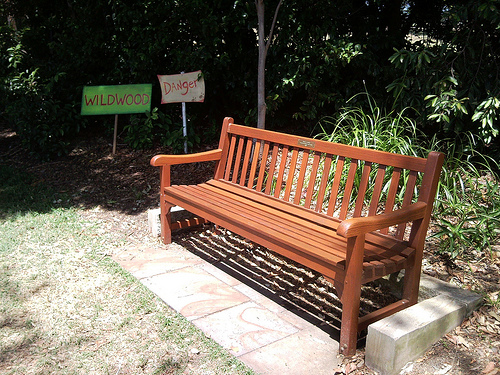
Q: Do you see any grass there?
A: Yes, there is grass.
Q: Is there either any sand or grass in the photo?
A: Yes, there is grass.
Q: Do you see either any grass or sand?
A: Yes, there is grass.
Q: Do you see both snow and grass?
A: No, there is grass but no snow.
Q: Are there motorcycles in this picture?
A: No, there are no motorcycles.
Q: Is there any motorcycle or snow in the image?
A: No, there are no motorcycles or snow.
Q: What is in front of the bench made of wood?
A: The grass is in front of the bench.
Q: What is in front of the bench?
A: The grass is in front of the bench.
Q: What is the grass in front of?
A: The grass is in front of the bench.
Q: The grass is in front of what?
A: The grass is in front of the bench.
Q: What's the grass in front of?
A: The grass is in front of the bench.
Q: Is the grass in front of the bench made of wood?
A: Yes, the grass is in front of the bench.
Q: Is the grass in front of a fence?
A: No, the grass is in front of the bench.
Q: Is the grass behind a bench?
A: No, the grass is in front of a bench.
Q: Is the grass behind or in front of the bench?
A: The grass is in front of the bench.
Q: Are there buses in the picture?
A: No, there are no buses.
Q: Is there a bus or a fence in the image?
A: No, there are no buses or fences.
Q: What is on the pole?
A: The sign is on the pole.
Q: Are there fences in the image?
A: No, there are no fences.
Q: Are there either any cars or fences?
A: No, there are no fences or cars.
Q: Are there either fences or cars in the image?
A: No, there are no fences or cars.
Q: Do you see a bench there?
A: Yes, there is a bench.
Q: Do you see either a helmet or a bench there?
A: Yes, there is a bench.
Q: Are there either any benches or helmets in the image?
A: Yes, there is a bench.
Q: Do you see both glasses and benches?
A: No, there is a bench but no glasses.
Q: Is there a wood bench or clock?
A: Yes, there is a wood bench.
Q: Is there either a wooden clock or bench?
A: Yes, there is a wood bench.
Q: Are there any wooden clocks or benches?
A: Yes, there is a wood bench.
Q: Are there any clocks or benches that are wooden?
A: Yes, the bench is wooden.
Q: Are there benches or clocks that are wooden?
A: Yes, the bench is wooden.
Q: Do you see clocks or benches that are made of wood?
A: Yes, the bench is made of wood.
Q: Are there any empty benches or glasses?
A: Yes, there is an empty bench.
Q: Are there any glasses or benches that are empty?
A: Yes, the bench is empty.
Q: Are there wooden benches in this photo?
A: Yes, there is a wood bench.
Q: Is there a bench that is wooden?
A: Yes, there is a bench that is wooden.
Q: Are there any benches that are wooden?
A: Yes, there is a bench that is wooden.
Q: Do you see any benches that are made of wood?
A: Yes, there is a bench that is made of wood.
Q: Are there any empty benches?
A: Yes, there is an empty bench.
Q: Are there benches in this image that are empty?
A: Yes, there is a bench that is empty.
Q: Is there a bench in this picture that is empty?
A: Yes, there is a bench that is empty.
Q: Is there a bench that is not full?
A: Yes, there is a empty bench.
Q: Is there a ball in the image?
A: No, there are no balls.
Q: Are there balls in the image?
A: No, there are no balls.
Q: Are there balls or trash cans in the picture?
A: No, there are no balls or trash cans.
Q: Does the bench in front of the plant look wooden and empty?
A: Yes, the bench is wooden and empty.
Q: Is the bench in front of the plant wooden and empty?
A: Yes, the bench is wooden and empty.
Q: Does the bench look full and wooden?
A: No, the bench is wooden but empty.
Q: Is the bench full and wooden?
A: No, the bench is wooden but empty.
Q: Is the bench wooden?
A: Yes, the bench is wooden.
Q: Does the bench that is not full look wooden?
A: Yes, the bench is wooden.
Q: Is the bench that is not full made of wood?
A: Yes, the bench is made of wood.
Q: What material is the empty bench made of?
A: The bench is made of wood.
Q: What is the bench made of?
A: The bench is made of wood.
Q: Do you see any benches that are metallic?
A: No, there is a bench but it is wooden.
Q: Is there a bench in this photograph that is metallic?
A: No, there is a bench but it is wooden.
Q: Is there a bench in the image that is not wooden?
A: No, there is a bench but it is wooden.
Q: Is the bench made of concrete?
A: No, the bench is made of wood.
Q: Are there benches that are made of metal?
A: No, there is a bench but it is made of wood.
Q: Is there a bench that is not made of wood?
A: No, there is a bench but it is made of wood.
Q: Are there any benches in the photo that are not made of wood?
A: No, there is a bench but it is made of wood.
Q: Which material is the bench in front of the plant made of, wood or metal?
A: The bench is made of wood.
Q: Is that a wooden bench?
A: Yes, that is a wooden bench.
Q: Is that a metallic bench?
A: No, that is a wooden bench.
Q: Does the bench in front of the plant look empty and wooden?
A: Yes, the bench is empty and wooden.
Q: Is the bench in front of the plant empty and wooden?
A: Yes, the bench is empty and wooden.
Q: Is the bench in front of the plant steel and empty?
A: No, the bench is empty but wooden.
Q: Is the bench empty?
A: Yes, the bench is empty.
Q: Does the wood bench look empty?
A: Yes, the bench is empty.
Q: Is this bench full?
A: No, the bench is empty.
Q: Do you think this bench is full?
A: No, the bench is empty.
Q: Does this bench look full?
A: No, the bench is empty.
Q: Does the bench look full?
A: No, the bench is empty.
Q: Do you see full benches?
A: No, there is a bench but it is empty.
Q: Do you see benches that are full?
A: No, there is a bench but it is empty.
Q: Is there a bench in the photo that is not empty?
A: No, there is a bench but it is empty.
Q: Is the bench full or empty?
A: The bench is empty.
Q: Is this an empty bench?
A: Yes, this is an empty bench.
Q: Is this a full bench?
A: No, this is an empty bench.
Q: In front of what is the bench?
A: The bench is in front of the plant.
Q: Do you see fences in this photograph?
A: No, there are no fences.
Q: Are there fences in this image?
A: No, there are no fences.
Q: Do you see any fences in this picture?
A: No, there are no fences.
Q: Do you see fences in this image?
A: No, there are no fences.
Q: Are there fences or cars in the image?
A: No, there are no fences or cars.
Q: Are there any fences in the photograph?
A: No, there are no fences.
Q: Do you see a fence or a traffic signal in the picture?
A: No, there are no fences or traffic lights.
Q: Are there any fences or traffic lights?
A: No, there are no fences or traffic lights.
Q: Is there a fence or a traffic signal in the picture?
A: No, there are no fences or traffic lights.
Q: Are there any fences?
A: No, there are no fences.